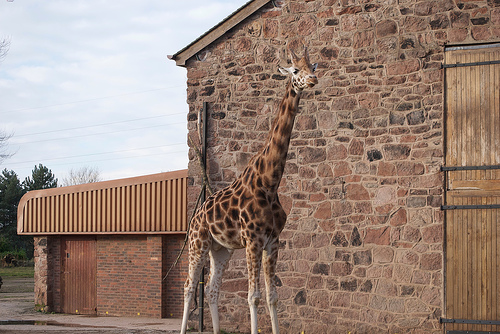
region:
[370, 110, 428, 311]
the walls are made of stine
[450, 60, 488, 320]
the door is wooden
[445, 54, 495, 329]
the door is brown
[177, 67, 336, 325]
the giraffe is tall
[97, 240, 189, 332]
the bricks are brown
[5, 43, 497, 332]
the photo was taken outside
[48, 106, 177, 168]
there are electrical lines in the air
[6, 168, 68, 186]
there are trees are in the background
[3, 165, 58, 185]
the trees have leaves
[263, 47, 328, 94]
the horns are small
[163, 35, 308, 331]
a giraffe looking at the camera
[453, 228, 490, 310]
wood panels in a door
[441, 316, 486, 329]
a black metal latch on the door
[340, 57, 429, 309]
a multicolored stone wall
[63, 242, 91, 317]
a wood paneled door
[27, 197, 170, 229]
wooden slats above the door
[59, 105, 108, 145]
white clouds in a blue sky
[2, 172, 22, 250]
green trees on the side of the building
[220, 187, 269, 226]
brown and white spots on the giraffe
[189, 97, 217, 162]
a black metal pole against the wall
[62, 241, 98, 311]
door frame in back of building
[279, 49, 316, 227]
standing giraffe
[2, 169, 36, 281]
evergreen backround trees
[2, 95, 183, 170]
power lines against sky background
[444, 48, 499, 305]
tall exterior door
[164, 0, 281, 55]
roof edge of building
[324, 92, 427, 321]
side of brick building behind standing giraffe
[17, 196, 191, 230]
lower roof are with smaller doors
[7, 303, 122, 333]
concrete ground covering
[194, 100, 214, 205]
black pole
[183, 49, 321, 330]
Brown and white giraffe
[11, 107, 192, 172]
Black power lines above the building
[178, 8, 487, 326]
Building with a stone wall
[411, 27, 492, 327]
Building with a tall wooden door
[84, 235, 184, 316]
Red and black brick wall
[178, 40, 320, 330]
The giraffe is standing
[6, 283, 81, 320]
The ground is dirt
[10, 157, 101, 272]
There are trees behind the building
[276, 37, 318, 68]
The giraffe has horns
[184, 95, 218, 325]
Long, black pole on side of building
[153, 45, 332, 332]
a tall giraffe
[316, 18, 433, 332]
a rock building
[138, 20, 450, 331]
a giraffe standing next to a rock building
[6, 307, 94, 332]
a puddle of water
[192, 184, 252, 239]
pattern on a giraffe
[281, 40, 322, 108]
two horns on a giraffe's head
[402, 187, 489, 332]
a wooden door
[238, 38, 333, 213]
a giraffes long neck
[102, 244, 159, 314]
a brick wall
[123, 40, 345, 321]
one giraffe standing by a building